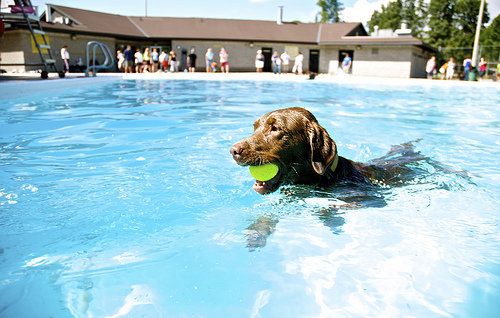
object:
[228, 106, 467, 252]
dog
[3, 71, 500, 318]
water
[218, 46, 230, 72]
people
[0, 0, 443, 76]
building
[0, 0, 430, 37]
sky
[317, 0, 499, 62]
trees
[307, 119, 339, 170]
ear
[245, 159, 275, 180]
ball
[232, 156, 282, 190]
mouth